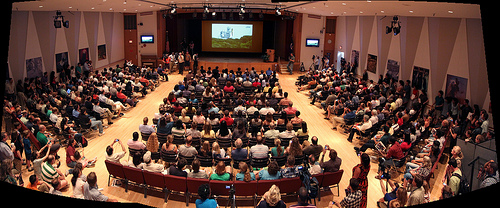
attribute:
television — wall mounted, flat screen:
[210, 24, 255, 53]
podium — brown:
[268, 48, 275, 62]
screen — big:
[197, 17, 267, 56]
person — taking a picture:
[103, 137, 130, 168]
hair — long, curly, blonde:
[145, 132, 159, 152]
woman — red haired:
[209, 160, 233, 180]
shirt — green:
[210, 172, 230, 179]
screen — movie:
[213, 24, 255, 48]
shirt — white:
[39, 161, 59, 186]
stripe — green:
[43, 162, 58, 177]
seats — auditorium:
[105, 160, 126, 190]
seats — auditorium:
[117, 162, 143, 190]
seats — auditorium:
[141, 170, 167, 202]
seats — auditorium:
[164, 174, 188, 202]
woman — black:
[215, 121, 233, 145]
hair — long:
[218, 120, 229, 135]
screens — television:
[126, 16, 387, 68]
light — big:
[384, 15, 406, 35]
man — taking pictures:
[309, 140, 347, 185]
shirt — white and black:
[337, 190, 364, 205]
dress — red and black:
[349, 164, 371, 204]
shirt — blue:
[213, 173, 237, 181]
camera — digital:
[112, 138, 118, 146]